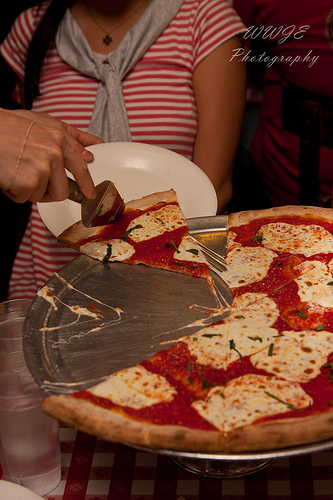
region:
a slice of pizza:
[52, 185, 217, 287]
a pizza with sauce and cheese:
[24, 216, 322, 423]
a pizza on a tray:
[34, 223, 327, 435]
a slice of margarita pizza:
[42, 302, 241, 448]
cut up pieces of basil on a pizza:
[194, 319, 315, 396]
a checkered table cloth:
[27, 417, 323, 498]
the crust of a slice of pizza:
[43, 389, 228, 465]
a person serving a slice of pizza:
[3, 99, 239, 289]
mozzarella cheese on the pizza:
[182, 290, 278, 368]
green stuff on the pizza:
[202, 330, 241, 358]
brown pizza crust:
[38, 392, 149, 443]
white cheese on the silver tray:
[37, 270, 127, 332]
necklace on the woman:
[80, 4, 138, 48]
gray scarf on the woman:
[52, 0, 184, 142]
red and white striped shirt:
[0, 0, 248, 298]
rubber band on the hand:
[9, 119, 35, 192]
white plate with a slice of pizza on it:
[32, 140, 218, 238]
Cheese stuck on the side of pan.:
[37, 275, 62, 319]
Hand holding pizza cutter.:
[16, 129, 127, 230]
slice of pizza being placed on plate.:
[58, 160, 208, 278]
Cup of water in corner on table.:
[0, 351, 62, 491]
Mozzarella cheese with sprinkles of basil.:
[195, 326, 248, 369]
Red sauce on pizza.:
[265, 278, 294, 299]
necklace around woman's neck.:
[92, 16, 118, 46]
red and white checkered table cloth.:
[70, 446, 132, 495]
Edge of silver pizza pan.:
[187, 450, 307, 466]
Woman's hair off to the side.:
[17, 8, 66, 95]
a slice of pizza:
[73, 205, 209, 292]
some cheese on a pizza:
[123, 200, 189, 237]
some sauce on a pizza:
[135, 223, 167, 262]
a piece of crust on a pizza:
[141, 185, 170, 206]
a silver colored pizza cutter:
[62, 185, 119, 226]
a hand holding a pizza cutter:
[2, 96, 104, 226]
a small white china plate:
[72, 131, 200, 202]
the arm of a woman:
[188, 41, 242, 166]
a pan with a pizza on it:
[73, 192, 323, 469]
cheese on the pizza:
[216, 325, 255, 354]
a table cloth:
[102, 468, 152, 497]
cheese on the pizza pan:
[51, 310, 101, 327]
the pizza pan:
[158, 289, 186, 311]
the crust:
[137, 426, 165, 444]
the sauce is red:
[160, 407, 191, 422]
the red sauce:
[164, 400, 189, 420]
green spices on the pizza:
[226, 332, 239, 348]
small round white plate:
[36, 141, 217, 245]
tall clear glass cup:
[0, 297, 61, 495]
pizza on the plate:
[53, 183, 219, 288]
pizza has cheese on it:
[67, 196, 205, 277]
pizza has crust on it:
[53, 381, 326, 461]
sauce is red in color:
[79, 210, 206, 279]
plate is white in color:
[28, 144, 221, 221]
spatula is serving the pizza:
[58, 175, 140, 229]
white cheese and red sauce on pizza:
[93, 235, 138, 259]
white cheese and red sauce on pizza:
[114, 377, 147, 402]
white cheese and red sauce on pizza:
[185, 398, 220, 416]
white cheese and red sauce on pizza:
[230, 364, 273, 416]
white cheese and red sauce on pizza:
[196, 338, 225, 371]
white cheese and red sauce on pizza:
[231, 310, 259, 346]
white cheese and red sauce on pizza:
[279, 331, 308, 372]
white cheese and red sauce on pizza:
[259, 224, 291, 253]